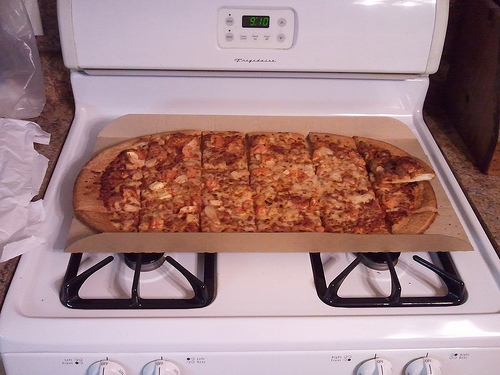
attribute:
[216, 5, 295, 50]
clock — digital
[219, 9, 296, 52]
buttons — gray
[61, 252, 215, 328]
burner — black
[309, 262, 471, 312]
burner — black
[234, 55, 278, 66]
logo — frigidaire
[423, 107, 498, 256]
countertop — granite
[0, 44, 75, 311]
countertop — granite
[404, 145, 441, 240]
crust — brown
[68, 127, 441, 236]
pizza — large, oval-shaped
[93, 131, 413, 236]
sauce — red